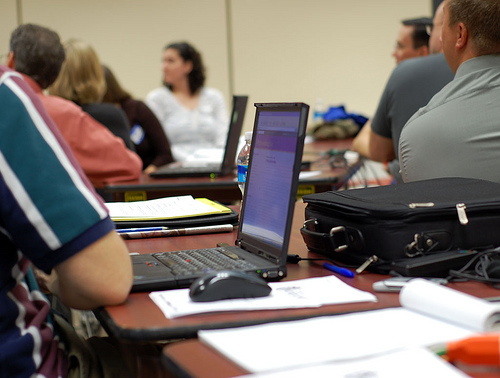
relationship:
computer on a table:
[101, 98, 311, 297] [111, 279, 491, 376]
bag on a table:
[299, 167, 498, 288] [133, 278, 498, 371]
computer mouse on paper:
[188, 272, 273, 302] [152, 265, 380, 335]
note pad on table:
[195, 281, 495, 375] [74, 199, 474, 376]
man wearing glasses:
[356, 4, 470, 163] [417, 17, 444, 32]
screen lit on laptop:
[250, 115, 298, 250] [122, 95, 308, 298]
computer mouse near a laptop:
[188, 272, 273, 302] [111, 80, 315, 292]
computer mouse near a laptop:
[188, 272, 273, 302] [101, 85, 314, 305]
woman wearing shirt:
[130, 41, 238, 163] [149, 87, 250, 178]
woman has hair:
[39, 29, 176, 173] [42, 36, 115, 103]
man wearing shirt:
[2, 21, 149, 188] [13, 66, 151, 188]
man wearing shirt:
[0, 73, 144, 375] [0, 76, 119, 376]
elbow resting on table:
[78, 247, 138, 311] [87, 221, 493, 368]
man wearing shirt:
[356, 4, 470, 163] [372, 54, 452, 168]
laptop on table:
[122, 95, 308, 298] [87, 221, 493, 368]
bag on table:
[299, 167, 498, 288] [87, 221, 493, 368]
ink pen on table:
[323, 262, 355, 279] [87, 221, 493, 368]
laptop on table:
[145, 91, 252, 179] [94, 160, 252, 202]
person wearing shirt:
[392, 8, 498, 177] [392, 61, 496, 177]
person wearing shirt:
[344, 0, 455, 175] [370, 51, 457, 146]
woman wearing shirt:
[130, 41, 238, 163] [144, 87, 234, 167]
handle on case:
[289, 210, 362, 250] [297, 174, 494, 280]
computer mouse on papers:
[188, 272, 273, 302] [143, 251, 363, 323]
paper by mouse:
[220, 305, 487, 371] [175, 261, 288, 299]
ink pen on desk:
[323, 262, 355, 279] [64, 182, 498, 336]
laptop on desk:
[108, 84, 297, 285] [70, 194, 497, 359]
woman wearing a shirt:
[130, 41, 238, 163] [146, 84, 244, 176]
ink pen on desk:
[312, 249, 359, 283] [70, 194, 497, 359]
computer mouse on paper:
[188, 272, 273, 302] [148, 278, 386, 321]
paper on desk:
[155, 269, 378, 319] [68, 178, 488, 363]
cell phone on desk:
[364, 271, 445, 298] [70, 194, 497, 359]